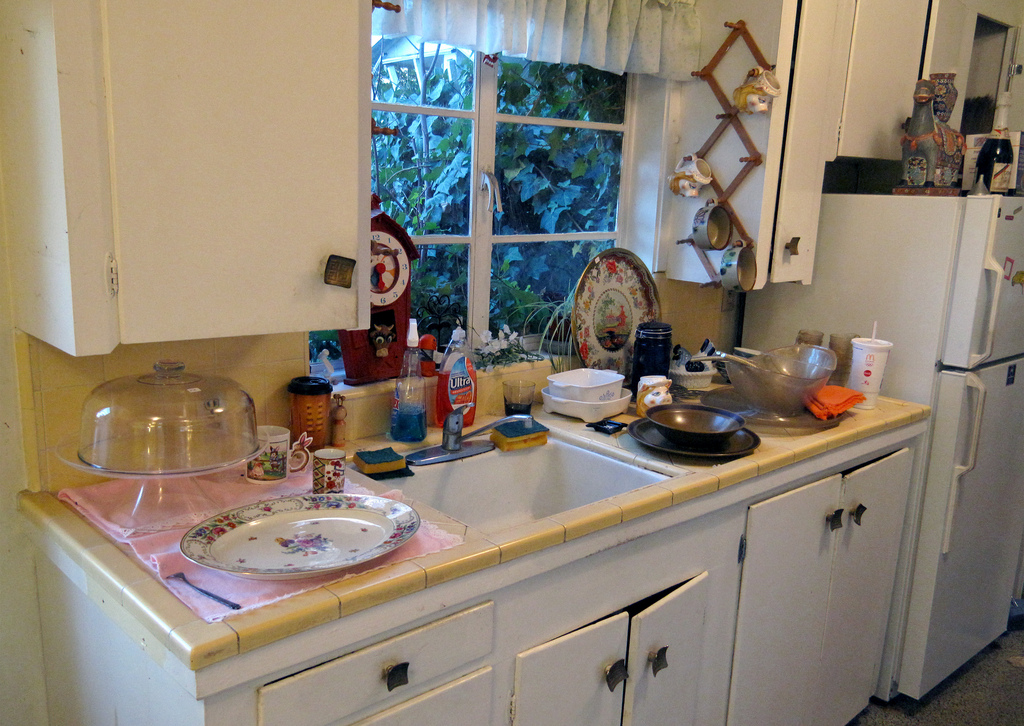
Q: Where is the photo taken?
A: In a kitchen.